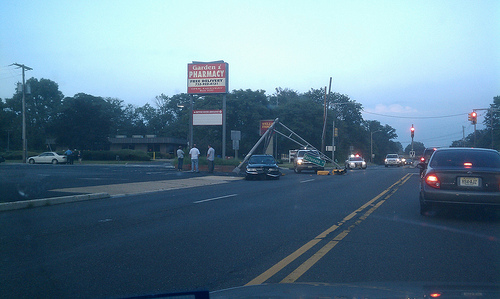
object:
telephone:
[5, 55, 32, 164]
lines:
[243, 172, 413, 286]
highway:
[0, 161, 499, 298]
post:
[330, 117, 336, 160]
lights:
[409, 126, 414, 130]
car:
[419, 147, 499, 219]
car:
[419, 147, 435, 175]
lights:
[469, 112, 477, 118]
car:
[26, 150, 68, 164]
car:
[243, 154, 283, 181]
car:
[343, 153, 367, 170]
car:
[384, 153, 403, 168]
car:
[292, 149, 326, 173]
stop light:
[410, 124, 413, 136]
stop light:
[468, 111, 477, 125]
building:
[107, 129, 187, 158]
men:
[188, 143, 201, 173]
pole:
[221, 94, 227, 157]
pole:
[187, 94, 195, 152]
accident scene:
[232, 117, 347, 180]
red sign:
[186, 62, 229, 93]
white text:
[189, 64, 224, 78]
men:
[205, 143, 215, 174]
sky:
[0, 0, 499, 151]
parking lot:
[7, 120, 193, 209]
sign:
[260, 118, 274, 138]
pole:
[273, 121, 342, 168]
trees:
[0, 75, 136, 150]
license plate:
[460, 176, 480, 186]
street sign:
[259, 117, 276, 154]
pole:
[232, 117, 279, 172]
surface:
[244, 196, 420, 282]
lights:
[350, 153, 359, 158]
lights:
[426, 175, 439, 183]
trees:
[140, 86, 364, 159]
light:
[297, 160, 302, 166]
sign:
[193, 109, 224, 126]